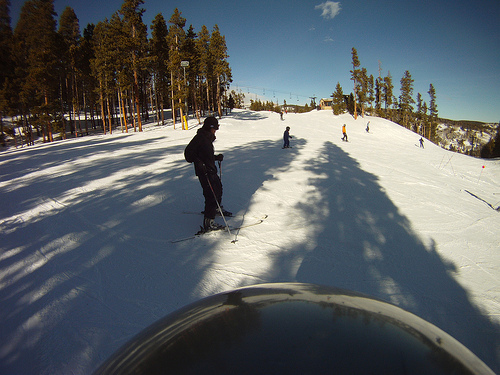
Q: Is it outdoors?
A: Yes, it is outdoors.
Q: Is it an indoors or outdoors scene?
A: It is outdoors.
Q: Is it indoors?
A: No, it is outdoors.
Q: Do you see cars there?
A: No, there are no cars.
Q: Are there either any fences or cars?
A: No, there are no cars or fences.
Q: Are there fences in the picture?
A: No, there are no fences.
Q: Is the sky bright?
A: Yes, the sky is bright.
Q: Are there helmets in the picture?
A: Yes, there is a helmet.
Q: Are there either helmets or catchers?
A: Yes, there is a helmet.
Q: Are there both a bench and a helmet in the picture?
A: No, there is a helmet but no benches.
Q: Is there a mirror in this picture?
A: No, there are no mirrors.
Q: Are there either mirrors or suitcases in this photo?
A: No, there are no mirrors or suitcases.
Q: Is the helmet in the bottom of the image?
A: Yes, the helmet is in the bottom of the image.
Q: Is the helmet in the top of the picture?
A: No, the helmet is in the bottom of the image.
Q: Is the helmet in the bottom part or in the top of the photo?
A: The helmet is in the bottom of the image.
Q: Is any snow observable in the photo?
A: Yes, there is snow.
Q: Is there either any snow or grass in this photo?
A: Yes, there is snow.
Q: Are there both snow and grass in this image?
A: No, there is snow but no grass.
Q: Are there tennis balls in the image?
A: No, there are no tennis balls.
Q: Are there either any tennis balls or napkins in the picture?
A: No, there are no tennis balls or napkins.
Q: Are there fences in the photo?
A: No, there are no fences.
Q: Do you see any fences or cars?
A: No, there are no fences or cars.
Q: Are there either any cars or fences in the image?
A: No, there are no fences or cars.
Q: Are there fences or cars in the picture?
A: No, there are no fences or cars.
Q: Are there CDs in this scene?
A: No, there are no cds.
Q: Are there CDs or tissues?
A: No, there are no CDs or tissues.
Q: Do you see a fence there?
A: No, there are no fences.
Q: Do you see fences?
A: No, there are no fences.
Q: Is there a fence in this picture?
A: No, there are no fences.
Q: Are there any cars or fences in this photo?
A: No, there are no fences or cars.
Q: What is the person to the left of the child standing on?
A: The person is standing on the ski.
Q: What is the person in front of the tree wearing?
A: The person is wearing trousers.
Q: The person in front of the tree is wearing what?
A: The person is wearing trousers.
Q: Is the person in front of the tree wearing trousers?
A: Yes, the person is wearing trousers.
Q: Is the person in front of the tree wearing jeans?
A: No, the person is wearing trousers.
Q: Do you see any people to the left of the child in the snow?
A: Yes, there is a person to the left of the kid.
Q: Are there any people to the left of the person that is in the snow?
A: Yes, there is a person to the left of the kid.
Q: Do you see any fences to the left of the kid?
A: No, there is a person to the left of the kid.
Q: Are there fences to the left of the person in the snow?
A: No, there is a person to the left of the kid.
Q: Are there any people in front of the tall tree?
A: Yes, there is a person in front of the tree.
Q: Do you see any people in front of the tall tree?
A: Yes, there is a person in front of the tree.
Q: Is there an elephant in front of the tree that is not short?
A: No, there is a person in front of the tree.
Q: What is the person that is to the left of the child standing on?
A: The person is standing on the ski.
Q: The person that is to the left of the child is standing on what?
A: The person is standing on the ski.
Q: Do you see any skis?
A: Yes, there are skis.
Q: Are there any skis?
A: Yes, there are skis.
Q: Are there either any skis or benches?
A: Yes, there are skis.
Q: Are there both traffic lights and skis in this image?
A: No, there are skis but no traffic lights.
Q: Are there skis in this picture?
A: Yes, there are skis.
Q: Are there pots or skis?
A: Yes, there are skis.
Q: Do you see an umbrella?
A: No, there are no umbrellas.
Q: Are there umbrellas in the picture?
A: No, there are no umbrellas.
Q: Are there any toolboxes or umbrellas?
A: No, there are no umbrellas or toolboxes.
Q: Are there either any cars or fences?
A: No, there are no cars or fences.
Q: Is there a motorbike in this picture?
A: No, there are no motorcycles.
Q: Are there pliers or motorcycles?
A: No, there are no motorcycles or pliers.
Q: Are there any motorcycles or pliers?
A: No, there are no motorcycles or pliers.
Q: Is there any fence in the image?
A: No, there are no fences.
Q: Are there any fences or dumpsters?
A: No, there are no fences or dumpsters.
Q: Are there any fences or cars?
A: No, there are no cars or fences.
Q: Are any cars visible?
A: No, there are no cars.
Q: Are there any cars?
A: No, there are no cars.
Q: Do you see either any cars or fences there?
A: No, there are no cars or fences.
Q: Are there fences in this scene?
A: No, there are no fences.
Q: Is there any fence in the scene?
A: No, there are no fences.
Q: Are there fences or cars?
A: No, there are no fences or cars.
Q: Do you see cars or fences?
A: No, there are no fences or cars.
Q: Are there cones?
A: No, there are no cones.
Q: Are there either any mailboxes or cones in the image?
A: No, there are no cones or mailboxes.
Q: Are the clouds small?
A: Yes, the clouds are small.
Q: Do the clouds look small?
A: Yes, the clouds are small.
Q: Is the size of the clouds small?
A: Yes, the clouds are small.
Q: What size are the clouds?
A: The clouds are small.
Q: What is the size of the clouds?
A: The clouds are small.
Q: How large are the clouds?
A: The clouds are small.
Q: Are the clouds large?
A: No, the clouds are small.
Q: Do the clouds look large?
A: No, the clouds are small.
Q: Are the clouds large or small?
A: The clouds are small.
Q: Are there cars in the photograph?
A: No, there are no cars.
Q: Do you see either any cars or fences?
A: No, there are no cars or fences.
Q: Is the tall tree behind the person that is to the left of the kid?
A: Yes, the tree is behind the person.